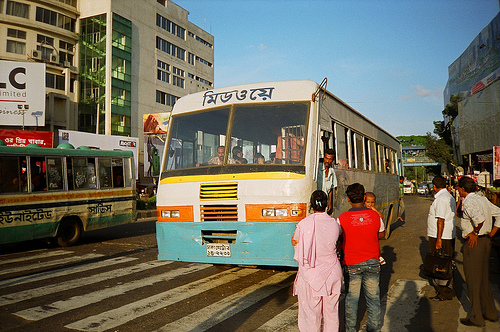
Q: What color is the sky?
A: Blue.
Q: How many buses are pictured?
A: Two.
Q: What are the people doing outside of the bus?
A: Waiting.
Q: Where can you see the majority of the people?
A: Front of bus window.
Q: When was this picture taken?
A: During afternoon.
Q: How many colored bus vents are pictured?
A: Two.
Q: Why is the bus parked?
A: At a stop.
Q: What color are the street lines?
A: White.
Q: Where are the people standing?
A: Bus stop.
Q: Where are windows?
A: On buildings.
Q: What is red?
A: Man's shirt.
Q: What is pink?
A: Woman's outfit.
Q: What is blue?
A: Sky.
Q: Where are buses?
A: In the street.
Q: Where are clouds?
A: In the sky.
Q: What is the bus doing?
A: Picking up passengers.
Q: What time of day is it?
A: Daytime.